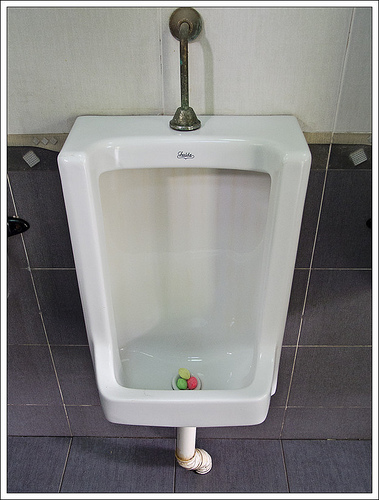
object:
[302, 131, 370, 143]
beige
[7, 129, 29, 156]
trim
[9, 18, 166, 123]
tiles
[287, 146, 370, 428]
tiles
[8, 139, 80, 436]
tiles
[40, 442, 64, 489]
tiles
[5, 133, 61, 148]
beige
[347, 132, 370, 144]
trim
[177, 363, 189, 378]
urinal cake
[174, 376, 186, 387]
cake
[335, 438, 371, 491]
tile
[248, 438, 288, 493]
tile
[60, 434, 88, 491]
tile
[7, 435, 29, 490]
tile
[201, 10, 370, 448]
wall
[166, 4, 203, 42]
circle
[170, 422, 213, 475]
drain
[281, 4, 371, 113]
off-white tiles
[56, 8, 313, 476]
bathroom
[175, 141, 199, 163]
name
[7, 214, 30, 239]
object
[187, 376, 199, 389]
balls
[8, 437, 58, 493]
floor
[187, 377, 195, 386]
urinal cake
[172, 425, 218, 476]
pipe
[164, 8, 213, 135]
flush pipe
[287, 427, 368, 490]
floor